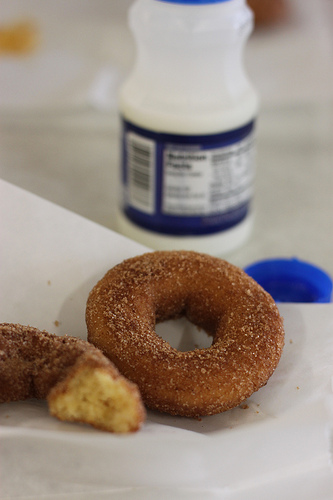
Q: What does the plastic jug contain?
A: Milk.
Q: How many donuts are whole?
A: One.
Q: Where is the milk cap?
A: On the table.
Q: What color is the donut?
A: Brown.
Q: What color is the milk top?
A: Blue.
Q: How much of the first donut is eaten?
A: Half.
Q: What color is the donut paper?
A: White.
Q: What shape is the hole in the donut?
A: Pentagon.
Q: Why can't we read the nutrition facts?
A: Out of focus.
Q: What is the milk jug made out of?
A: Plastic.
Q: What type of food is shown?
A: Donuts.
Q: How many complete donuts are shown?
A: 1.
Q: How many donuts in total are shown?
A: 2.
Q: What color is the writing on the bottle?
A: Black.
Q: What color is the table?
A: White.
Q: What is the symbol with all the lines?
A: Bar code.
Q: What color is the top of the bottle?
A: Blue.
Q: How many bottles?
A: 1.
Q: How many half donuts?
A: 1.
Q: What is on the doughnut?
A: Sugar and cinnamon.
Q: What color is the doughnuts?
A: Brown.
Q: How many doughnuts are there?
A: Two.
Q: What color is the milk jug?
A: White and blue.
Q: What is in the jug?
A: Milk.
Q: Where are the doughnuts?
A: On a plate.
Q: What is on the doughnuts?
A: Sugar.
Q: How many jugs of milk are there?
A: One.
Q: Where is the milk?
A: By the doughnuts.